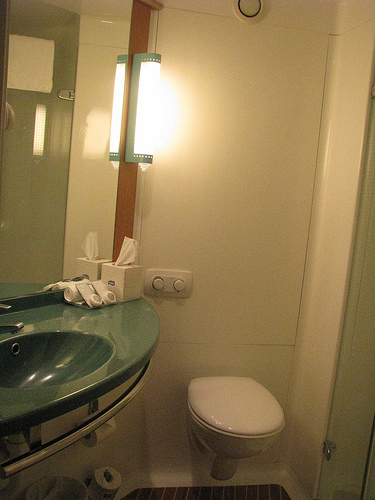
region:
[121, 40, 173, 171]
a light on the mirror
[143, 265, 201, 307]
knobs on the wall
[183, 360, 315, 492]
a toilet on the wall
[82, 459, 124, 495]
a roll of toilet paper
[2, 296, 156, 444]
a green sink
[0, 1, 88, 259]
a reflection of a door in a mirror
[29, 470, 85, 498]
a garbage can that can barely be seen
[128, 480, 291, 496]
a barely noticeable part of a floor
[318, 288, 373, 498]
a light green door in the bathroom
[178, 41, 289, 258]
a tan wall in the background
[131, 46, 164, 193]
the light is on the wall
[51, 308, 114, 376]
the counter top is green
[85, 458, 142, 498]
a extra roll of toilet paper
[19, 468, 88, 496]
trash can under the counter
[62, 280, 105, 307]
white towel rolled up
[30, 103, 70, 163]
reflection of the light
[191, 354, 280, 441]
the toilet is white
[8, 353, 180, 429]
metal rail under the counter top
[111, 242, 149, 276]
the tissue is white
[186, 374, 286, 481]
A shiny white toilet.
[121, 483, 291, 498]
Brown tile on floor.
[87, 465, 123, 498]
A new roll of toilet paper.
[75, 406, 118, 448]
A roll of toilet paper.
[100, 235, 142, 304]
A box of tissue.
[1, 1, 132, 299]
A mirror on the wall.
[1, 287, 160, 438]
A green bathroom sink.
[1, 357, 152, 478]
A shiny chrome bar.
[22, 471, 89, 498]
A trash and bag.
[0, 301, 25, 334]
Part of a faucet.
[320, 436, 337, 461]
Shower stall bracket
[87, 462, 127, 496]
Packaged toilet paper roll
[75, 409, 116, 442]
Unpackaged toilet paper roll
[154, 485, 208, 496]
Titles on bathroom floor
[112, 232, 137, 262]
Paper tissue coming out of dispenser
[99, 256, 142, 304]
Tissue dispenser on sink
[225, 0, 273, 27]
Fire alarm on wall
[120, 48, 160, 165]
Vanity light on the wall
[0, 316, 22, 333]
Spigot on bathroom sink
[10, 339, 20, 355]
Overflow drain on sink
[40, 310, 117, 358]
The sink is green.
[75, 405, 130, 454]
A roll of toilet paper is under the sink.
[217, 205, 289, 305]
The wall is white.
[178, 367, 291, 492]
The toilet is white.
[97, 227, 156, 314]
A box of tissues are sitting on the sink.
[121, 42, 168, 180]
A light by the sink.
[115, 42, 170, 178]
The light is on.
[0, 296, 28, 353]
A faucet is on the sink.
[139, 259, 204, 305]
Knobs are on the wall.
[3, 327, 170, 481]
A rail is under the sink.